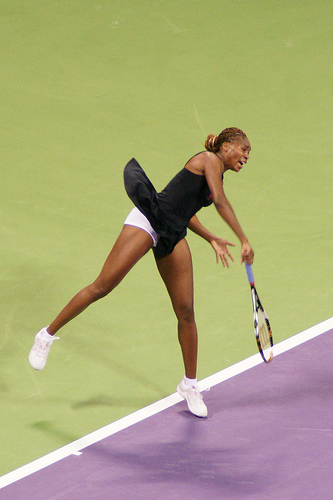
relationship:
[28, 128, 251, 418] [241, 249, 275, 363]
person holding racket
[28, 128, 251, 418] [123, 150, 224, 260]
person wearing black dress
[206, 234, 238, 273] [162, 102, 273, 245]
hand of person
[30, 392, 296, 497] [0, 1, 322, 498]
shadow on ground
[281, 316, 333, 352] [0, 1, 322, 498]
paint on ground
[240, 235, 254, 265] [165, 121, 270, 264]
hand of person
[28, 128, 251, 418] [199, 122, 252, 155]
person has hair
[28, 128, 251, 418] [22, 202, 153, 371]
person has leg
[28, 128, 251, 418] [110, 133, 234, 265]
person wearing dress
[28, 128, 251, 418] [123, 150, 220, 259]
person wearing dress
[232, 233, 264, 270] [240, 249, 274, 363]
hand holding racket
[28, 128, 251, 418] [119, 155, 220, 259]
person wearing black dress